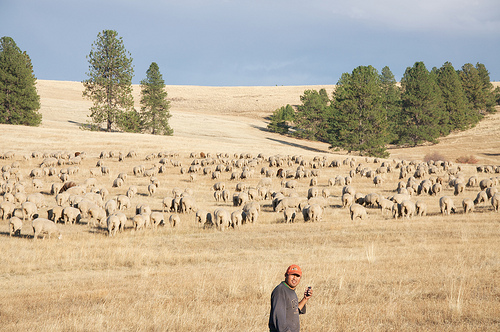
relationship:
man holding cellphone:
[263, 261, 303, 329] [306, 286, 312, 297]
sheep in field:
[161, 150, 411, 228] [5, 121, 496, 248]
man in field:
[263, 261, 303, 329] [5, 121, 496, 248]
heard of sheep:
[273, 177, 341, 208] [161, 150, 411, 228]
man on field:
[263, 261, 303, 329] [5, 121, 496, 248]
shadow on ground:
[271, 131, 306, 150] [210, 89, 258, 137]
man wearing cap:
[263, 261, 303, 329] [284, 264, 303, 277]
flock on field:
[255, 149, 371, 199] [5, 121, 496, 248]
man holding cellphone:
[267, 263, 316, 331] [302, 284, 313, 297]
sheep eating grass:
[161, 150, 411, 228] [201, 94, 257, 123]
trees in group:
[309, 71, 488, 121] [329, 59, 476, 152]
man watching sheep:
[263, 261, 303, 329] [161, 150, 411, 228]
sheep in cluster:
[161, 150, 411, 228] [2, 148, 495, 225]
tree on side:
[1, 37, 45, 130] [1, 3, 50, 168]